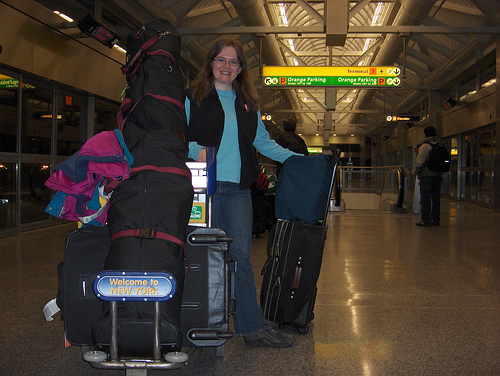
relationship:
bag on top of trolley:
[89, 18, 195, 359] [80, 270, 190, 373]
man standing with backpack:
[409, 124, 445, 226] [419, 139, 444, 174]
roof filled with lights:
[77, 0, 496, 137] [267, 0, 395, 122]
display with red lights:
[51, 11, 121, 49] [91, 22, 113, 45]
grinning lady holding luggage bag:
[183, 39, 307, 350] [261, 217, 318, 312]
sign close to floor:
[93, 270, 179, 304] [336, 205, 495, 370]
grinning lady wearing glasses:
[183, 39, 307, 350] [208, 51, 243, 67]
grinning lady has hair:
[183, 39, 307, 350] [183, 37, 258, 111]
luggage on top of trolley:
[53, 225, 238, 354] [80, 270, 190, 373]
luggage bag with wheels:
[259, 217, 328, 335] [280, 314, 316, 336]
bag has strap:
[96, 25, 186, 350] [131, 42, 180, 67]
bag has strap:
[96, 25, 186, 350] [119, 90, 191, 111]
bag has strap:
[96, 25, 186, 350] [117, 163, 196, 185]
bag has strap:
[96, 25, 186, 350] [123, 225, 184, 242]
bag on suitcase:
[272, 142, 334, 227] [252, 211, 329, 344]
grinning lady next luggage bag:
[183, 39, 307, 350] [259, 217, 328, 335]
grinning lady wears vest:
[183, 39, 307, 350] [187, 84, 258, 186]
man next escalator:
[411, 124, 446, 225] [333, 162, 405, 207]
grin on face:
[215, 67, 237, 77] [217, 46, 237, 81]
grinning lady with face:
[183, 39, 297, 354] [217, 46, 237, 81]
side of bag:
[68, 165, 310, 363] [105, 15, 194, 358]